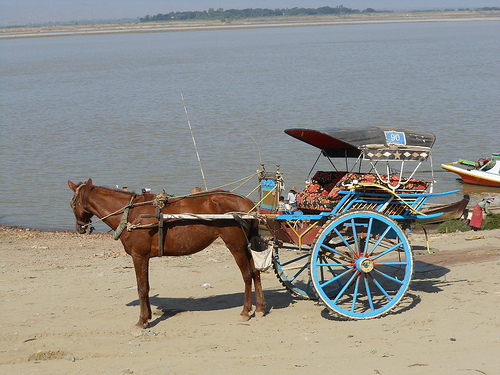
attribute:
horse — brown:
[61, 171, 281, 332]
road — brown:
[8, 238, 493, 372]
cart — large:
[235, 116, 465, 325]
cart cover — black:
[272, 120, 446, 160]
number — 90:
[382, 129, 407, 147]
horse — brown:
[47, 171, 269, 326]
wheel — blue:
[307, 216, 417, 334]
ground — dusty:
[172, 326, 303, 371]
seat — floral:
[292, 169, 397, 216]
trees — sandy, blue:
[140, 6, 373, 25]